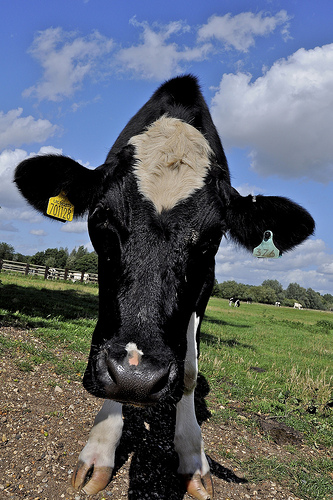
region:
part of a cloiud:
[247, 74, 266, 100]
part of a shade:
[131, 425, 145, 455]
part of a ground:
[251, 444, 276, 488]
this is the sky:
[31, 12, 148, 109]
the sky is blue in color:
[66, 126, 98, 141]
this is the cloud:
[247, 69, 330, 134]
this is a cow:
[83, 122, 306, 464]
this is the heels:
[183, 470, 214, 489]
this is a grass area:
[251, 312, 329, 380]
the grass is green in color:
[275, 311, 303, 358]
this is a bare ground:
[24, 393, 69, 439]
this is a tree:
[259, 279, 271, 296]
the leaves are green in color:
[226, 281, 238, 288]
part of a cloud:
[229, 72, 261, 114]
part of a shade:
[143, 449, 162, 473]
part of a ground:
[250, 413, 293, 458]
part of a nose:
[130, 376, 154, 395]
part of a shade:
[217, 449, 246, 481]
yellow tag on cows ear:
[12, 155, 90, 223]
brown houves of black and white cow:
[181, 467, 214, 498]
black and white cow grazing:
[227, 296, 241, 311]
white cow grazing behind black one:
[292, 301, 302, 310]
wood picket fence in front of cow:
[39, 264, 69, 281]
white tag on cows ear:
[240, 194, 316, 258]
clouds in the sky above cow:
[202, 8, 295, 48]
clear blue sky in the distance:
[3, 4, 52, 25]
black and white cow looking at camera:
[28, 74, 313, 407]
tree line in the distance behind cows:
[243, 279, 322, 299]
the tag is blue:
[247, 228, 282, 258]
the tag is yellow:
[38, 181, 81, 223]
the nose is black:
[109, 363, 154, 398]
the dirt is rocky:
[26, 401, 56, 449]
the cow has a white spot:
[139, 112, 195, 192]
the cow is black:
[126, 217, 172, 298]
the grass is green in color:
[249, 327, 275, 352]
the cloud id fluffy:
[261, 91, 298, 134]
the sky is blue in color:
[105, 91, 125, 114]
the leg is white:
[91, 404, 121, 450]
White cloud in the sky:
[2, 102, 54, 158]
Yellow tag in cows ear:
[42, 189, 80, 227]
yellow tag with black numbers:
[45, 189, 76, 222]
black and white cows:
[13, 72, 314, 499]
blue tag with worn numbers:
[249, 228, 279, 260]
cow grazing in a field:
[227, 295, 241, 310]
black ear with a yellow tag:
[12, 152, 107, 223]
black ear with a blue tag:
[221, 184, 315, 261]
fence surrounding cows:
[2, 258, 97, 285]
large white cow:
[291, 300, 302, 309]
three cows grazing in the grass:
[227, 294, 304, 312]